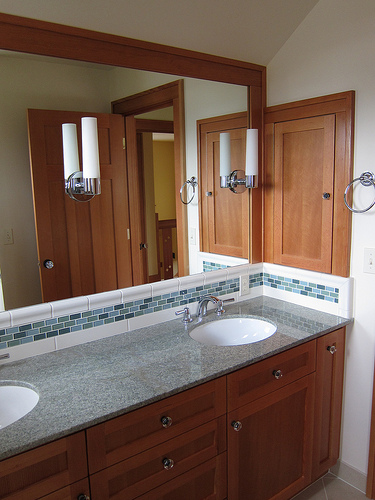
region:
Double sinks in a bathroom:
[2, 2, 373, 495]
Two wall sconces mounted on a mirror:
[64, 111, 263, 203]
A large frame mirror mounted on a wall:
[0, 11, 265, 311]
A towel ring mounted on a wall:
[340, 172, 373, 220]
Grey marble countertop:
[1, 290, 358, 466]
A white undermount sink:
[185, 312, 279, 347]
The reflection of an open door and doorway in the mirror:
[26, 78, 187, 301]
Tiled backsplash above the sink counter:
[1, 261, 358, 362]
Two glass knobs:
[158, 413, 178, 473]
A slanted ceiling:
[4, 1, 337, 69]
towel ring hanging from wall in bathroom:
[342, 174, 369, 214]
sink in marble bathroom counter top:
[188, 316, 280, 341]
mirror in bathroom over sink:
[1, 51, 261, 263]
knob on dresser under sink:
[157, 416, 172, 429]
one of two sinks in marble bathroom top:
[0, 372, 43, 425]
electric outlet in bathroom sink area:
[237, 274, 252, 294]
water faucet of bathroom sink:
[193, 294, 217, 316]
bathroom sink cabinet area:
[25, 444, 341, 498]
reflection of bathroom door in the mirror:
[29, 107, 144, 283]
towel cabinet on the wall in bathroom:
[270, 109, 342, 262]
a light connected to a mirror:
[63, 110, 107, 200]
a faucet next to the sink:
[175, 294, 225, 322]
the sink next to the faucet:
[188, 313, 278, 348]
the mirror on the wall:
[0, 49, 252, 306]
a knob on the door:
[230, 418, 242, 430]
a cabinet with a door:
[260, 107, 344, 270]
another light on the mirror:
[219, 128, 257, 196]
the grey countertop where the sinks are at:
[0, 295, 351, 462]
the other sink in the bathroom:
[2, 376, 38, 429]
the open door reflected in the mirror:
[22, 96, 182, 288]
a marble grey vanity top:
[0, 296, 353, 466]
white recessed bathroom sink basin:
[187, 312, 274, 344]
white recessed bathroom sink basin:
[0, 377, 38, 425]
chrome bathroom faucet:
[172, 293, 229, 325]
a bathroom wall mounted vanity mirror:
[0, 51, 252, 312]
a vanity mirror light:
[66, 114, 105, 202]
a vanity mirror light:
[229, 126, 260, 194]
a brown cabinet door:
[268, 113, 337, 271]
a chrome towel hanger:
[340, 173, 373, 213]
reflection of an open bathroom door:
[115, 105, 183, 286]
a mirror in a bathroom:
[4, 12, 263, 313]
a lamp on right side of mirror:
[225, 122, 262, 190]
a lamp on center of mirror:
[51, 108, 106, 204]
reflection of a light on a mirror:
[55, 115, 81, 195]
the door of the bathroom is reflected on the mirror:
[20, 95, 142, 302]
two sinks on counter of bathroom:
[3, 286, 352, 458]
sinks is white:
[183, 313, 278, 349]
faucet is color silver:
[193, 293, 227, 323]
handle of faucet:
[171, 301, 194, 323]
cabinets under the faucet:
[137, 371, 350, 493]